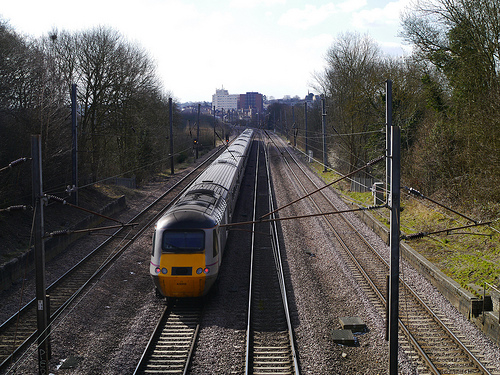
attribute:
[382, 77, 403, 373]
pole — brown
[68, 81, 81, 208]
pole — straight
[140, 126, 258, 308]
train — yellow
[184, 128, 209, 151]
light — on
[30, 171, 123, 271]
retaining wall — cement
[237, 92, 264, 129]
building — white, brown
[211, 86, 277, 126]
buildings — multi-story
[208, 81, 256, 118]
building — tall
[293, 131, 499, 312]
grass — mossy, green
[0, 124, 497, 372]
tracks — train, four sets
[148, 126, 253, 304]
train — gray, orange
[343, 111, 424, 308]
pole — straight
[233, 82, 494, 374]
pole — metal, horizontal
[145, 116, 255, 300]
train — yellow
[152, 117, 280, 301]
train — travelling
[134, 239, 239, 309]
front — yellow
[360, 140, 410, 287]
poles — metal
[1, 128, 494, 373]
rails — metallic